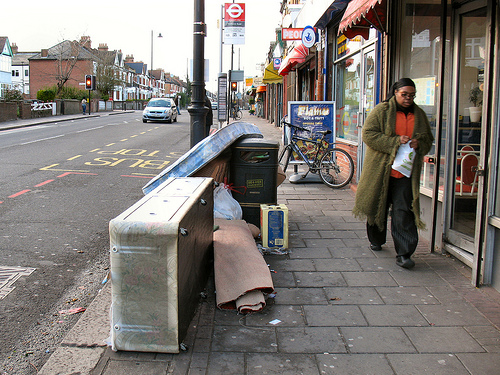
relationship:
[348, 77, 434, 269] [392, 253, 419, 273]
woman wearing shoe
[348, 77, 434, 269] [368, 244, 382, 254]
woman wearing shoe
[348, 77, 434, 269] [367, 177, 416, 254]
woman wearing pants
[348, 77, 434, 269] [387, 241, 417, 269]
woman wearing shoe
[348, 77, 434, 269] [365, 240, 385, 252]
woman wearing shoe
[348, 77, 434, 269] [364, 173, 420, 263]
woman wearing pants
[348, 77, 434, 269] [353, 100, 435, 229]
woman wearing coat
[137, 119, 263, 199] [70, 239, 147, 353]
mattress on curb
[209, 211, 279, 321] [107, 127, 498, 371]
carpet on sidewalk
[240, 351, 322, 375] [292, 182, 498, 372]
block in sidewalk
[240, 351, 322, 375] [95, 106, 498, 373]
block in sidewalk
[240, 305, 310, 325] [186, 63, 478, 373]
block on sidewalk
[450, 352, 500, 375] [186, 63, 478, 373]
block on sidewalk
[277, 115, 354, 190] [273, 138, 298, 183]
bicycle with tire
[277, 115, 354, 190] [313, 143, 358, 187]
bicycle with tire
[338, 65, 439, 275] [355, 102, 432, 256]
woman wearing coat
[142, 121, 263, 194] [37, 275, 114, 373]
mattress tossed out to curb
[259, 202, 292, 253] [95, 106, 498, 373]
trash stacked on sidewalk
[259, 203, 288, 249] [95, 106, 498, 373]
trash stacked on sidewalk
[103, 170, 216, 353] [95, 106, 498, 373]
trash stacked on sidewalk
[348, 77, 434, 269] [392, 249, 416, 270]
woman wearing shoe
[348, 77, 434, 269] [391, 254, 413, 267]
woman wearing shoe